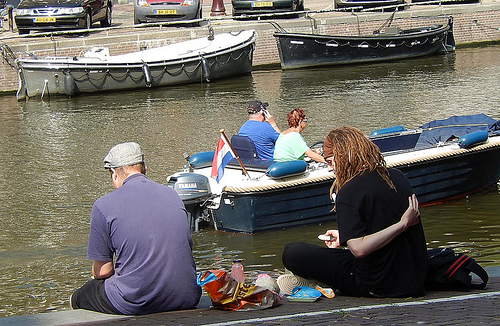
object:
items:
[196, 263, 335, 312]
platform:
[0, 266, 500, 326]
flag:
[209, 128, 253, 184]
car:
[15, 0, 112, 35]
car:
[131, 0, 203, 26]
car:
[229, 0, 305, 21]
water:
[1, 42, 498, 315]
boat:
[163, 113, 500, 234]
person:
[281, 126, 431, 299]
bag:
[427, 248, 488, 292]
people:
[237, 100, 329, 165]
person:
[238, 101, 281, 159]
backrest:
[231, 135, 258, 159]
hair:
[327, 125, 398, 213]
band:
[323, 135, 333, 159]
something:
[317, 234, 330, 240]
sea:
[0, 102, 88, 258]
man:
[68, 141, 207, 318]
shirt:
[89, 173, 201, 316]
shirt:
[272, 132, 309, 162]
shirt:
[237, 120, 280, 161]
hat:
[247, 101, 269, 113]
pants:
[281, 240, 361, 296]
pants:
[70, 277, 123, 315]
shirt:
[332, 166, 432, 298]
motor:
[165, 171, 212, 205]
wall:
[457, 13, 499, 41]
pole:
[219, 129, 250, 180]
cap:
[103, 142, 145, 169]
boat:
[14, 29, 256, 103]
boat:
[272, 16, 456, 71]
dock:
[4, 6, 485, 89]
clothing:
[282, 168, 427, 298]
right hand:
[325, 229, 342, 248]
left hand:
[401, 194, 421, 227]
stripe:
[445, 254, 469, 279]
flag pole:
[218, 128, 254, 180]